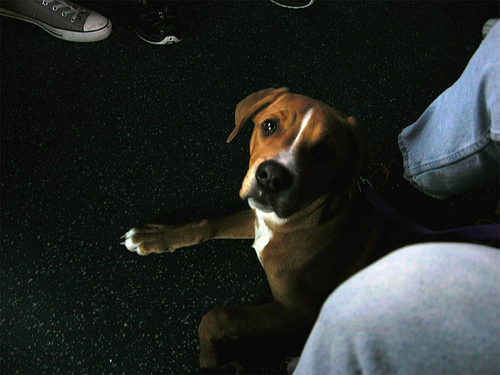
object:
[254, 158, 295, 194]
nose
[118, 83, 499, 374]
dog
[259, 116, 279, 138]
eye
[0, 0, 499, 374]
ground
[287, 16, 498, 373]
man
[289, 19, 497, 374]
jeans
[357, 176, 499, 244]
leash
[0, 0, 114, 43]
shoe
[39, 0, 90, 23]
lace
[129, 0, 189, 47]
shoe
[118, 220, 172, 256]
paw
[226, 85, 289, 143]
ear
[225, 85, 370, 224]
head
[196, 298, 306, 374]
front leg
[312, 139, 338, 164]
left eye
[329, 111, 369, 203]
left ear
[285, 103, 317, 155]
marking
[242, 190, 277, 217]
mouth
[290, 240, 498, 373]
knee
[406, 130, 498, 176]
seam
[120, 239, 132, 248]
toe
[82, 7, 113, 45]
tip